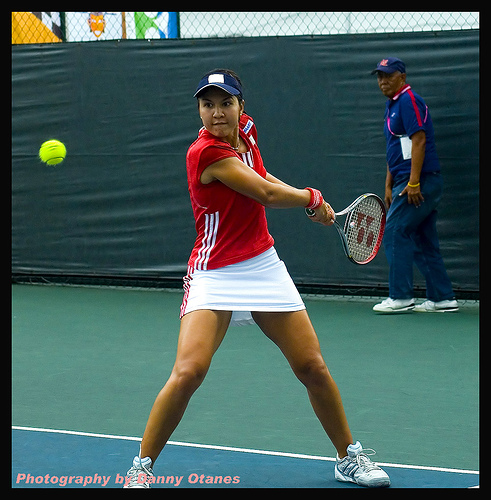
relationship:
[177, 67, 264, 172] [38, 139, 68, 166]
woman hitting a tennis ball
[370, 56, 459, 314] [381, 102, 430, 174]
coach wearing blue uniform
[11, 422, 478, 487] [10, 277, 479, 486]
markings on tennis court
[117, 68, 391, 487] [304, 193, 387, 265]
player holding racket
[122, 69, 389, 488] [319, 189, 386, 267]
woman holding tennis racket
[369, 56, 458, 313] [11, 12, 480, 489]
man standing on side of court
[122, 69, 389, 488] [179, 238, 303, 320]
woman wearing skirt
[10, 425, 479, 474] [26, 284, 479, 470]
line on court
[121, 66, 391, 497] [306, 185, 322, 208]
lady wearing wristband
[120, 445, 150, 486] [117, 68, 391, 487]
shoe of player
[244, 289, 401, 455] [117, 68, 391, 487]
leg of player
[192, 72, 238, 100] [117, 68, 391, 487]
cap of player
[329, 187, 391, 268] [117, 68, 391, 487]
racket of player